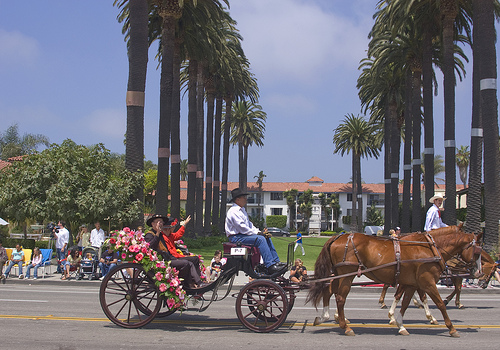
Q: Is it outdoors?
A: Yes, it is outdoors.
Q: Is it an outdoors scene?
A: Yes, it is outdoors.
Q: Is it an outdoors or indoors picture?
A: It is outdoors.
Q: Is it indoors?
A: No, it is outdoors.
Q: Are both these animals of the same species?
A: Yes, all the animals are horses.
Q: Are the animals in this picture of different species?
A: No, all the animals are horses.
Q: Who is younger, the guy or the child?
A: The child is younger than the guy.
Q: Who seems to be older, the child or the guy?
A: The guy is older than the child.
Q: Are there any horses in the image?
A: Yes, there is a horse.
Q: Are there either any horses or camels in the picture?
A: Yes, there is a horse.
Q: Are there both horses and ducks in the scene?
A: No, there is a horse but no ducks.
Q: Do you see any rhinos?
A: No, there are no rhinos.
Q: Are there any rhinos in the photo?
A: No, there are no rhinos.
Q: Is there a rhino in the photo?
A: No, there are no rhinos.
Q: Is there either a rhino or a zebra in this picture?
A: No, there are no rhinos or zebras.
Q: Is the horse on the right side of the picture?
A: Yes, the horse is on the right of the image.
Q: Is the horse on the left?
A: No, the horse is on the right of the image.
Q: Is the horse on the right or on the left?
A: The horse is on the right of the image.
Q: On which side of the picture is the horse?
A: The horse is on the right of the image.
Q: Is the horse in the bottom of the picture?
A: Yes, the horse is in the bottom of the image.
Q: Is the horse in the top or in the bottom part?
A: The horse is in the bottom of the image.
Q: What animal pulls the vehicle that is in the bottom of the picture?
A: The horse pulls the carriage.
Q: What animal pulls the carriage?
A: The horse pulls the carriage.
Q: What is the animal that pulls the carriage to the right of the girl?
A: The animal is a horse.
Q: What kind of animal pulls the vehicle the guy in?
A: The animal is a horse.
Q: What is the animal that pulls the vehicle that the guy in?
A: The animal is a horse.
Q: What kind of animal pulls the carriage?
A: The animal is a horse.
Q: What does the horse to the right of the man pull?
A: The horse pulls the carriage.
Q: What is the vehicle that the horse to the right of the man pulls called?
A: The vehicle is a carriage.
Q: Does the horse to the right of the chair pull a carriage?
A: Yes, the horse pulls a carriage.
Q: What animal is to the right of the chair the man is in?
A: The animal is a horse.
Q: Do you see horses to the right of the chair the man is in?
A: Yes, there is a horse to the right of the chair.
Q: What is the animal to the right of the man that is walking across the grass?
A: The animal is a horse.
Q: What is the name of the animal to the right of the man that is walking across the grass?
A: The animal is a horse.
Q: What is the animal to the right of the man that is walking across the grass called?
A: The animal is a horse.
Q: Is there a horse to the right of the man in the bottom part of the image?
A: Yes, there is a horse to the right of the man.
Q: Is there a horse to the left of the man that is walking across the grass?
A: No, the horse is to the right of the man.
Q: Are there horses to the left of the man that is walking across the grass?
A: No, the horse is to the right of the man.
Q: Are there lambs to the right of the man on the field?
A: No, there is a horse to the right of the man.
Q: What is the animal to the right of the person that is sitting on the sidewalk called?
A: The animal is a horse.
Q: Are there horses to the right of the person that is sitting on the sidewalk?
A: Yes, there is a horse to the right of the person.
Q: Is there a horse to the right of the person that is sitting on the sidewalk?
A: Yes, there is a horse to the right of the person.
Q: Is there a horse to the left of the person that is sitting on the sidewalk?
A: No, the horse is to the right of the person.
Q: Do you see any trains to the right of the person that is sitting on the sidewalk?
A: No, there is a horse to the right of the person.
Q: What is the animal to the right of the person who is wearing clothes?
A: The animal is a horse.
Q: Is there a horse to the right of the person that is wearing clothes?
A: Yes, there is a horse to the right of the person.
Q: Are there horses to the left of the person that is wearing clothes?
A: No, the horse is to the right of the person.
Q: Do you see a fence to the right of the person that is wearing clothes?
A: No, there is a horse to the right of the person.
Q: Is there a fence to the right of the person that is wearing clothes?
A: No, there is a horse to the right of the person.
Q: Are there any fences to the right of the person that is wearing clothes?
A: No, there is a horse to the right of the person.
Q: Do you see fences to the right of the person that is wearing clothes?
A: No, there is a horse to the right of the person.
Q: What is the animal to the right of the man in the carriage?
A: The animal is a horse.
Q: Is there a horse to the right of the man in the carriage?
A: Yes, there is a horse to the right of the man.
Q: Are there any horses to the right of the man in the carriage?
A: Yes, there is a horse to the right of the man.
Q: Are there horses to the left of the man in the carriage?
A: No, the horse is to the right of the man.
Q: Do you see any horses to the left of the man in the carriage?
A: No, the horse is to the right of the man.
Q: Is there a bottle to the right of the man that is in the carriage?
A: No, there is a horse to the right of the man.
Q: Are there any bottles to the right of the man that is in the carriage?
A: No, there is a horse to the right of the man.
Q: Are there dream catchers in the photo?
A: No, there are no dream catchers.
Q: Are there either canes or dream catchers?
A: No, there are no dream catchers or canes.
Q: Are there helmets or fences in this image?
A: No, there are no fences or helmets.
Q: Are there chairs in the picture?
A: Yes, there is a chair.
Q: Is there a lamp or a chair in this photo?
A: Yes, there is a chair.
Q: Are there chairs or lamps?
A: Yes, there is a chair.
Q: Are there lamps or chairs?
A: Yes, there is a chair.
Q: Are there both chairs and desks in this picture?
A: No, there is a chair but no desks.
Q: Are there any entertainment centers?
A: No, there are no entertainment centers.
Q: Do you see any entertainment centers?
A: No, there are no entertainment centers.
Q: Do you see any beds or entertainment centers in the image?
A: No, there are no entertainment centers or beds.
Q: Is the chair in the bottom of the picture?
A: Yes, the chair is in the bottom of the image.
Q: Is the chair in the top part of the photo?
A: No, the chair is in the bottom of the image.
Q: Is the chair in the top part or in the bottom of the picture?
A: The chair is in the bottom of the image.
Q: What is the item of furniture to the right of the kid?
A: The piece of furniture is a chair.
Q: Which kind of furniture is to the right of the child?
A: The piece of furniture is a chair.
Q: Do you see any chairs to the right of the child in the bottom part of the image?
A: Yes, there is a chair to the right of the child.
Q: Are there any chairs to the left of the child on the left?
A: No, the chair is to the right of the child.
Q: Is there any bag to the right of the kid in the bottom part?
A: No, there is a chair to the right of the kid.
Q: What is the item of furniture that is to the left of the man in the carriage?
A: The piece of furniture is a chair.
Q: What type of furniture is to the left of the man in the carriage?
A: The piece of furniture is a chair.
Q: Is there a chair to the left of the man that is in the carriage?
A: Yes, there is a chair to the left of the man.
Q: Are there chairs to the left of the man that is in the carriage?
A: Yes, there is a chair to the left of the man.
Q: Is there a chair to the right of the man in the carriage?
A: No, the chair is to the left of the man.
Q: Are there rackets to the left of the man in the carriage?
A: No, there is a chair to the left of the man.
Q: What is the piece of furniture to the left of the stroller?
A: The piece of furniture is a chair.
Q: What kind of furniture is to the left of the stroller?
A: The piece of furniture is a chair.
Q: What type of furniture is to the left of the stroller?
A: The piece of furniture is a chair.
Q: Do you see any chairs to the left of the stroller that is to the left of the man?
A: Yes, there is a chair to the left of the stroller.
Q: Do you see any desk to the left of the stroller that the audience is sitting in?
A: No, there is a chair to the left of the stroller.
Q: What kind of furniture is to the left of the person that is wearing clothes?
A: The piece of furniture is a chair.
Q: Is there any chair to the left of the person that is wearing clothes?
A: Yes, there is a chair to the left of the person.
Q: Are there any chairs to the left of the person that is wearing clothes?
A: Yes, there is a chair to the left of the person.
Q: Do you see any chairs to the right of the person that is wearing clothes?
A: No, the chair is to the left of the person.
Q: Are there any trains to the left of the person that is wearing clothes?
A: No, there is a chair to the left of the person.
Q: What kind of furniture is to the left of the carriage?
A: The piece of furniture is a chair.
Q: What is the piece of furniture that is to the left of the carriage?
A: The piece of furniture is a chair.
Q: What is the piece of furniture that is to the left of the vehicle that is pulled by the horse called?
A: The piece of furniture is a chair.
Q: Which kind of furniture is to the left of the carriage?
A: The piece of furniture is a chair.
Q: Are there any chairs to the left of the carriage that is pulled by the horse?
A: Yes, there is a chair to the left of the carriage.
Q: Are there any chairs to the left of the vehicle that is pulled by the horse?
A: Yes, there is a chair to the left of the carriage.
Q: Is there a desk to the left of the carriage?
A: No, there is a chair to the left of the carriage.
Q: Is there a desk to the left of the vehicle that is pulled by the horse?
A: No, there is a chair to the left of the carriage.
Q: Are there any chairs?
A: Yes, there is a chair.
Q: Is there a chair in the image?
A: Yes, there is a chair.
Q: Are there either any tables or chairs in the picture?
A: Yes, there is a chair.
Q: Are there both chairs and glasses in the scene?
A: No, there is a chair but no glasses.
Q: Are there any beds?
A: No, there are no beds.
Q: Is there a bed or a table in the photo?
A: No, there are no beds or tables.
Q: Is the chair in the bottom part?
A: Yes, the chair is in the bottom of the image.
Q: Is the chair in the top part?
A: No, the chair is in the bottom of the image.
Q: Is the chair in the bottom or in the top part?
A: The chair is in the bottom of the image.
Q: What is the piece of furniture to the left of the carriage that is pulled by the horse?
A: The piece of furniture is a chair.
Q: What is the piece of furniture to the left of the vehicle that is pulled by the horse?
A: The piece of furniture is a chair.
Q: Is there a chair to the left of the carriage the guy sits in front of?
A: Yes, there is a chair to the left of the carriage.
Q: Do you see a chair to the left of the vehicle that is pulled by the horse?
A: Yes, there is a chair to the left of the carriage.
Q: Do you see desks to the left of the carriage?
A: No, there is a chair to the left of the carriage.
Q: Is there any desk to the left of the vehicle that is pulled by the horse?
A: No, there is a chair to the left of the carriage.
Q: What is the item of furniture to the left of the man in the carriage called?
A: The piece of furniture is a chair.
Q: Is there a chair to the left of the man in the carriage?
A: Yes, there is a chair to the left of the man.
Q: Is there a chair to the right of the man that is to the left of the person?
A: No, the chair is to the left of the man.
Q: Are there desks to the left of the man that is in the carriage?
A: No, there is a chair to the left of the man.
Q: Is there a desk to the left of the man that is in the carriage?
A: No, there is a chair to the left of the man.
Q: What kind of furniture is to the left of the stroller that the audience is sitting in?
A: The piece of furniture is a chair.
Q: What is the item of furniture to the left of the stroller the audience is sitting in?
A: The piece of furniture is a chair.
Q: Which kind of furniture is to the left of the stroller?
A: The piece of furniture is a chair.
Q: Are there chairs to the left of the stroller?
A: Yes, there is a chair to the left of the stroller.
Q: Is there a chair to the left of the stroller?
A: Yes, there is a chair to the left of the stroller.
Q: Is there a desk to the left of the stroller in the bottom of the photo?
A: No, there is a chair to the left of the stroller.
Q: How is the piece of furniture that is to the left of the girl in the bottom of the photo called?
A: The piece of furniture is a chair.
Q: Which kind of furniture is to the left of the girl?
A: The piece of furniture is a chair.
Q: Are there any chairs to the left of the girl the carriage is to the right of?
A: Yes, there is a chair to the left of the girl.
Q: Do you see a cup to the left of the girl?
A: No, there is a chair to the left of the girl.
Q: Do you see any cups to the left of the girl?
A: No, there is a chair to the left of the girl.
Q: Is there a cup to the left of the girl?
A: No, there is a chair to the left of the girl.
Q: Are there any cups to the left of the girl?
A: No, there is a chair to the left of the girl.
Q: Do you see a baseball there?
A: No, there are no baseballs.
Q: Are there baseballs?
A: No, there are no baseballs.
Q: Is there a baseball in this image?
A: No, there are no baseballs.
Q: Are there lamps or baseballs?
A: No, there are no baseballs or lamps.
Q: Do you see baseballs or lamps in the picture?
A: No, there are no baseballs or lamps.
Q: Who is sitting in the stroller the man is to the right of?
A: The audience is sitting in the stroller.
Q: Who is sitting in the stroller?
A: The audience is sitting in the stroller.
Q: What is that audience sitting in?
A: The audience is sitting in the stroller.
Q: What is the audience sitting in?
A: The audience is sitting in the stroller.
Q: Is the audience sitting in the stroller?
A: Yes, the audience is sitting in the stroller.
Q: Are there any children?
A: Yes, there is a child.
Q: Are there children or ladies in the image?
A: Yes, there is a child.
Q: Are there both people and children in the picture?
A: Yes, there are both a child and a person.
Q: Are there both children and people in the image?
A: Yes, there are both a child and a person.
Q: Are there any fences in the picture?
A: No, there are no fences.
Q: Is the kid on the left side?
A: Yes, the kid is on the left of the image.